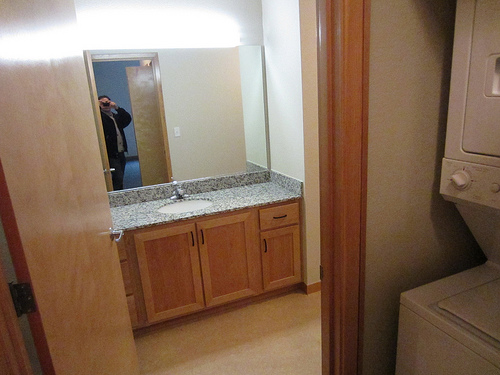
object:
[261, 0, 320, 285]
white wall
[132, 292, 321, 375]
floor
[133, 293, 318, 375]
ground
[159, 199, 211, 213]
sink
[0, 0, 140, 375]
door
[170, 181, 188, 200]
tap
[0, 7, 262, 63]
bright light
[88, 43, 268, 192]
large mirror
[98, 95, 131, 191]
man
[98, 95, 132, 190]
photographer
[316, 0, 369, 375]
frame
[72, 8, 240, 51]
light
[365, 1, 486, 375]
wall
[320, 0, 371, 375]
wood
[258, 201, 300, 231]
drawers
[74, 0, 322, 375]
bathroom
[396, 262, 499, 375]
washer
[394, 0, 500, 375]
dryer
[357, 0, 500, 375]
room corner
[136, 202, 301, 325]
cabinet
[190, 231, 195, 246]
handle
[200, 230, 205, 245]
handle